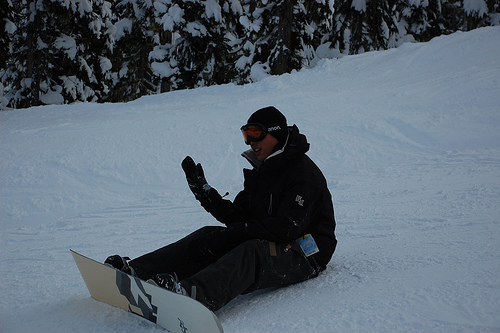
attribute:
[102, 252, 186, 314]
boots — snowboarder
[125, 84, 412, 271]
his clothes — black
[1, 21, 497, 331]
snow — white, dusty, thick, powdery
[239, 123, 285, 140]
reflective goggles — large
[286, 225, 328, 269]
station tag — ski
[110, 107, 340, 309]
gear — snow 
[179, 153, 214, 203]
gloves — snow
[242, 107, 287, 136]
hat — black, snow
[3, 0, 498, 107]
branches — tree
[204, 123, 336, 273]
jacket — black, anti wind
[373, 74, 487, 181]
snow — white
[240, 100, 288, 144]
goggles — black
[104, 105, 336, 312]
snowsuit — dark, large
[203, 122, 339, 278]
coat — black, winter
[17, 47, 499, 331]
snowboard — gold, white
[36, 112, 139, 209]
snow — dust white 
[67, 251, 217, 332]
snowboard — white, gray, tan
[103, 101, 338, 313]
guy — Asian, snowboarding 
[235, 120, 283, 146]
goggles — red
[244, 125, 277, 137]
lens — orange